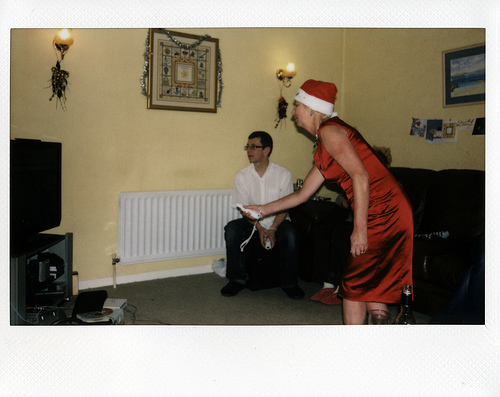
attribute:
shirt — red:
[310, 114, 415, 301]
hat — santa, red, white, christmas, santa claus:
[294, 78, 339, 114]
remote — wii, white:
[233, 200, 260, 251]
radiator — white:
[118, 191, 242, 260]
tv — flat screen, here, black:
[11, 137, 67, 257]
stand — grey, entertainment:
[12, 232, 75, 322]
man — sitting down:
[221, 130, 304, 299]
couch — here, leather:
[246, 167, 484, 318]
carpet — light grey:
[71, 272, 485, 324]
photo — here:
[409, 117, 428, 138]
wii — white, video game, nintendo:
[105, 293, 137, 325]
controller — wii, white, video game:
[265, 232, 272, 252]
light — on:
[55, 26, 72, 40]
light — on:
[287, 59, 293, 70]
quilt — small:
[45, 62, 69, 113]